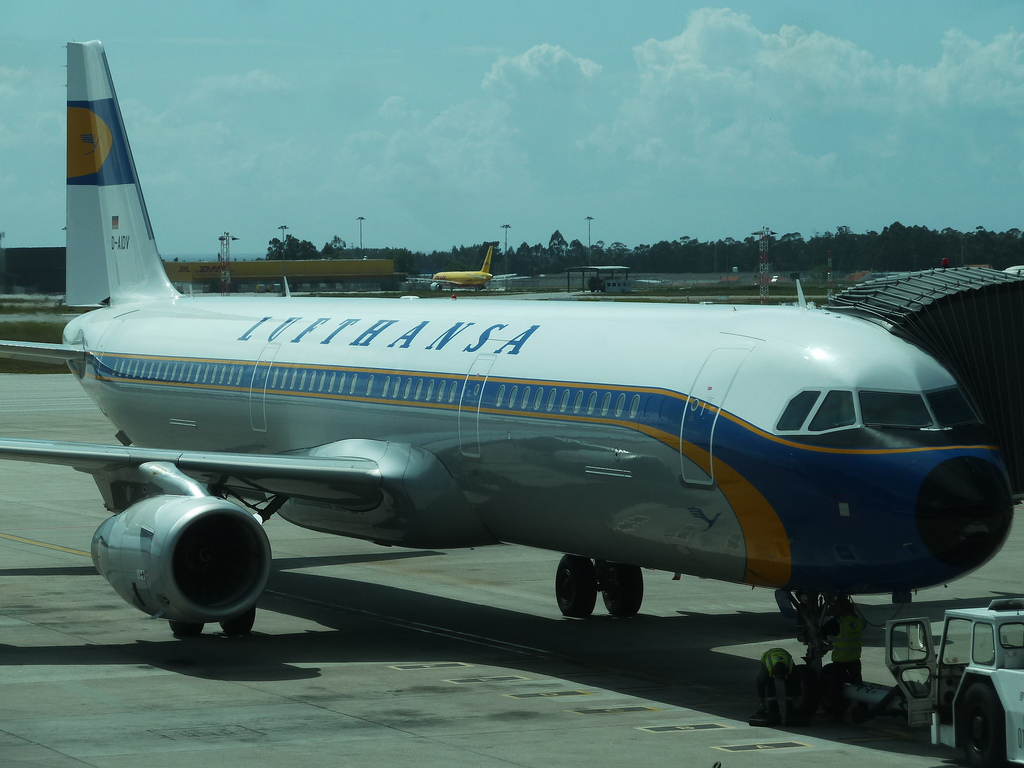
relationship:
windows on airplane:
[739, 330, 988, 464] [0, 39, 1011, 642]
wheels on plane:
[528, 509, 714, 616] [15, 51, 992, 618]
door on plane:
[690, 306, 777, 538] [24, 15, 992, 642]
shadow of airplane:
[346, 574, 766, 760] [0, 39, 1011, 642]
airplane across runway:
[0, 39, 1011, 642] [31, 345, 675, 762]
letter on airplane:
[498, 320, 538, 364] [4, 39, 1014, 714]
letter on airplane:
[108, 232, 130, 250] [4, 39, 1014, 714]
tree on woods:
[661, 245, 724, 267] [270, 223, 1009, 265]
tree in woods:
[290, 242, 321, 264] [262, 221, 1019, 273]